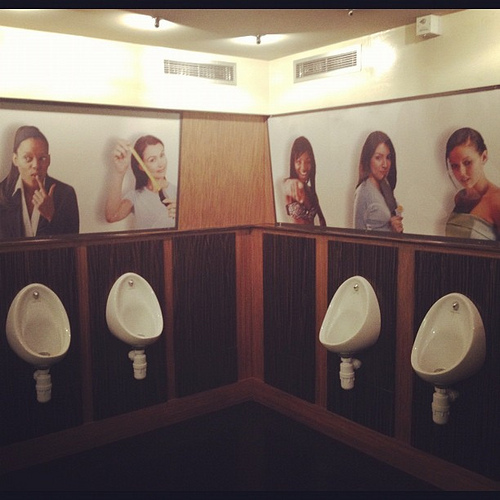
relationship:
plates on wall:
[159, 45, 371, 110] [1, 26, 253, 442]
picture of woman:
[266, 88, 498, 240] [284, 131, 324, 226]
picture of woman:
[266, 88, 498, 240] [350, 130, 406, 230]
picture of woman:
[266, 88, 498, 240] [440, 125, 484, 233]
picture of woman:
[0, 108, 189, 242] [9, 128, 85, 238]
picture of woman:
[0, 108, 189, 242] [105, 133, 178, 229]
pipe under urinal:
[418, 378, 474, 444] [397, 275, 495, 436]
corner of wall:
[211, 71, 318, 355] [0, 9, 249, 464]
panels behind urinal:
[3, 230, 498, 482] [3, 278, 74, 404]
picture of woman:
[266, 95, 484, 235] [282, 131, 494, 211]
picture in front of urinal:
[266, 95, 484, 235] [408, 290, 490, 425]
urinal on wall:
[408, 290, 490, 425] [270, 232, 479, 465]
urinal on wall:
[103, 270, 166, 380] [1, 102, 261, 478]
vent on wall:
[287, 41, 364, 92] [2, 9, 497, 117]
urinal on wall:
[3, 278, 74, 404] [0, 224, 250, 490]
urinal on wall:
[103, 270, 166, 380] [0, 224, 250, 490]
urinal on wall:
[318, 271, 386, 392] [247, 219, 498, 499]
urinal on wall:
[408, 290, 490, 425] [247, 219, 498, 499]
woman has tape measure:
[101, 135, 180, 236] [124, 142, 174, 202]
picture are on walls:
[0, 108, 189, 242] [4, 22, 491, 249]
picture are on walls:
[266, 88, 498, 240] [4, 22, 491, 249]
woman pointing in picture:
[278, 133, 326, 226] [268, 115, 345, 229]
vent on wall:
[168, 68, 232, 76] [149, 46, 257, 107]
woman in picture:
[278, 133, 326, 226] [266, 88, 498, 240]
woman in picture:
[347, 127, 404, 232] [266, 88, 498, 240]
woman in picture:
[443, 125, 498, 240] [266, 88, 498, 240]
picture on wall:
[266, 88, 498, 240] [267, 62, 496, 278]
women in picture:
[3, 119, 82, 239] [2, 98, 188, 245]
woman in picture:
[101, 135, 180, 236] [2, 98, 188, 245]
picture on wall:
[2, 98, 188, 245] [0, 95, 277, 245]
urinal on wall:
[408, 290, 490, 425] [415, 251, 495, 301]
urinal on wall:
[103, 270, 166, 380] [79, 235, 189, 441]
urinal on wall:
[11, 274, 73, 411] [0, 236, 255, 470]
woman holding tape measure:
[85, 100, 195, 217] [124, 142, 176, 210]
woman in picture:
[85, 100, 195, 217] [2, 98, 188, 245]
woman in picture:
[443, 125, 498, 240] [263, 85, 498, 247]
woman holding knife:
[347, 127, 404, 232] [381, 175, 398, 214]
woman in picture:
[347, 127, 404, 232] [347, 128, 404, 233]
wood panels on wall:
[0, 227, 499, 482] [0, 0, 499, 492]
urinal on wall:
[7, 278, 73, 399] [2, 223, 498, 498]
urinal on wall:
[103, 270, 166, 380] [2, 223, 498, 498]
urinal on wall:
[318, 271, 386, 392] [2, 223, 498, 498]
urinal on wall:
[408, 290, 490, 425] [2, 223, 498, 498]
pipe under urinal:
[124, 346, 152, 380] [100, 265, 171, 382]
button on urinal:
[30, 287, 38, 299] [3, 279, 75, 405]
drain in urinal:
[433, 366, 445, 373] [408, 290, 490, 425]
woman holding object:
[347, 127, 404, 232] [394, 206, 404, 220]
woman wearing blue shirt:
[347, 127, 404, 232] [356, 179, 403, 236]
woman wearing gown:
[443, 125, 498, 240] [444, 212, 498, 242]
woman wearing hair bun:
[443, 125, 498, 240] [443, 129, 488, 161]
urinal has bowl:
[318, 271, 386, 392] [314, 307, 373, 344]